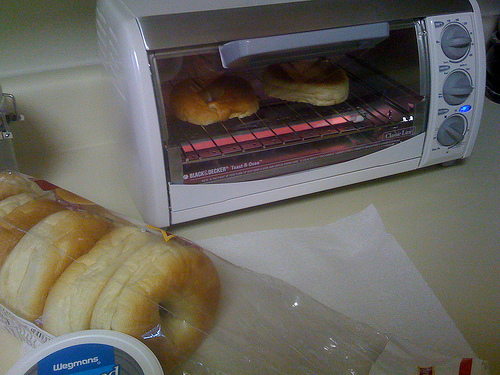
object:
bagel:
[169, 73, 260, 126]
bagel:
[261, 58, 352, 107]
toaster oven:
[94, 0, 489, 230]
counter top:
[0, 72, 500, 375]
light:
[181, 112, 367, 153]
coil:
[180, 103, 417, 185]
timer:
[431, 104, 474, 154]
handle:
[217, 19, 391, 70]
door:
[145, 14, 434, 211]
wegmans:
[48, 352, 103, 373]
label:
[35, 341, 128, 374]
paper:
[190, 201, 491, 375]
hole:
[205, 90, 216, 103]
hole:
[307, 74, 318, 82]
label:
[182, 158, 264, 181]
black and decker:
[189, 165, 229, 178]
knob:
[440, 23, 471, 60]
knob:
[442, 69, 474, 105]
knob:
[436, 115, 466, 146]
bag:
[0, 168, 492, 375]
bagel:
[89, 229, 226, 374]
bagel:
[39, 220, 163, 345]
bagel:
[0, 205, 117, 323]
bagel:
[0, 188, 72, 251]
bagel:
[0, 169, 46, 205]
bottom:
[167, 132, 479, 227]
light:
[458, 104, 472, 113]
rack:
[150, 17, 431, 184]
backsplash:
[1, 0, 500, 79]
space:
[220, 256, 394, 374]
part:
[434, 189, 500, 290]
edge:
[367, 200, 496, 375]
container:
[0, 327, 168, 375]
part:
[299, 240, 372, 291]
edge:
[92, 0, 172, 229]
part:
[415, 10, 489, 169]